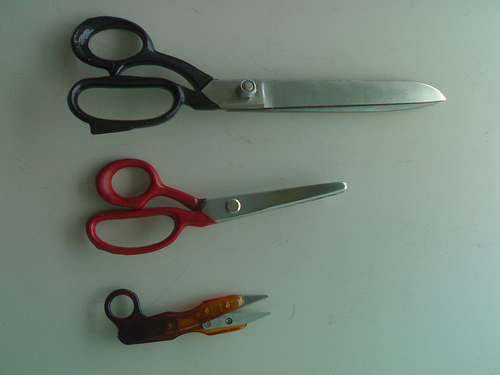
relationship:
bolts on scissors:
[237, 80, 261, 102] [66, 15, 448, 135]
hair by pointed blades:
[212, 336, 273, 375] [195, 292, 270, 352]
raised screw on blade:
[177, 293, 217, 323] [219, 289, 285, 375]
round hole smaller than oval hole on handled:
[89, 159, 176, 204] [83, 207, 216, 257]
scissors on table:
[83, 156, 350, 258] [102, 75, 453, 326]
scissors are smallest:
[101, 287, 277, 348] [102, 285, 273, 348]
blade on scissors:
[184, 282, 273, 359] [4, 155, 411, 235]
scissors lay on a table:
[63, 18, 462, 351] [2, 200, 474, 360]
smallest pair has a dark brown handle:
[86, 265, 274, 373] [91, 271, 178, 367]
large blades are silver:
[66, 14, 446, 134] [244, 193, 327, 268]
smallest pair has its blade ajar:
[102, 285, 273, 348] [111, 270, 263, 374]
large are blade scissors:
[66, 14, 446, 134] [63, 10, 451, 138]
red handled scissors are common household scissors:
[79, 166, 215, 323] [68, 155, 373, 267]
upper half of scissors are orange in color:
[200, 288, 256, 335] [172, 291, 259, 375]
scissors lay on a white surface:
[83, 156, 350, 256] [41, 51, 460, 297]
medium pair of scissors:
[81, 148, 352, 266] [48, 150, 365, 278]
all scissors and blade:
[67, 116, 322, 339] [240, 292, 269, 306]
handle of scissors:
[67, 15, 219, 133] [66, 15, 448, 135]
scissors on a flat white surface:
[63, 18, 462, 351] [43, 126, 440, 369]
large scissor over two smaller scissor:
[70, 50, 456, 127] [65, 14, 447, 134]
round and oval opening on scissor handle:
[98, 286, 143, 350] [43, 11, 245, 140]